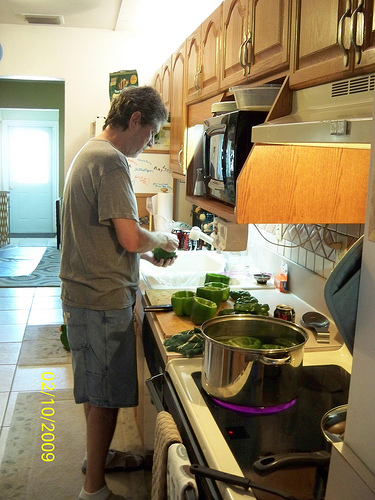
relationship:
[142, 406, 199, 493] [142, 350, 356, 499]
towels in stove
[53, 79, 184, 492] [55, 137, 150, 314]
man using t-shirt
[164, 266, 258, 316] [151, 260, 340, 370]
peppers on counter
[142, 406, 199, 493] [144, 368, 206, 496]
towels hanging oven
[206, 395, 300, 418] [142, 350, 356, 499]
lit burner on stove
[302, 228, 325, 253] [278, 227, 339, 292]
tile on wall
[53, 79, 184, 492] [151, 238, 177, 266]
man holding bell pepper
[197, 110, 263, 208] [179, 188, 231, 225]
microwave on a shelf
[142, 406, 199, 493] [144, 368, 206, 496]
towels on door handle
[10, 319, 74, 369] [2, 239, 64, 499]
rug on floor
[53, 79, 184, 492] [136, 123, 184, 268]
man looking down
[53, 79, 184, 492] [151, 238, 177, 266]
man with bell pepper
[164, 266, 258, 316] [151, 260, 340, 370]
bell peppers on counter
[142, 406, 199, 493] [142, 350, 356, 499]
towels hanging on stove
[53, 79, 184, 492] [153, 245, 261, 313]
man cutting bell peppers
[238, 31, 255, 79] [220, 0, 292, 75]
handles on cabinet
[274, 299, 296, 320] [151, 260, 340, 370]
soda on top counter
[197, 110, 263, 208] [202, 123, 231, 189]
microwave has black door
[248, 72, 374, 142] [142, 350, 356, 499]
hood above stove